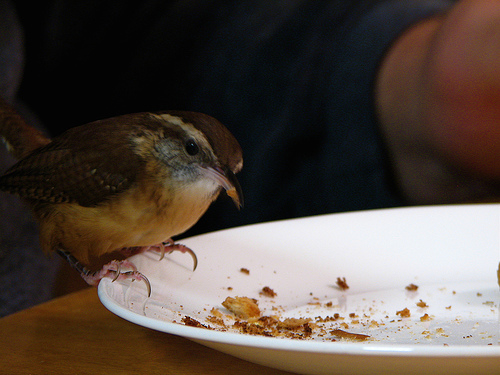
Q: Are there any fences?
A: No, there are no fences.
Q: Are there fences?
A: No, there are no fences.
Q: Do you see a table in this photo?
A: Yes, there is a table.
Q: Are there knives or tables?
A: Yes, there is a table.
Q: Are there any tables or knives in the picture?
A: Yes, there is a table.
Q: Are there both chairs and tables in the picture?
A: No, there is a table but no chairs.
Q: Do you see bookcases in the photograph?
A: No, there are no bookcases.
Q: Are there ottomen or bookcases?
A: No, there are no bookcases or ottomen.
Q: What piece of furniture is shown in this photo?
A: The piece of furniture is a table.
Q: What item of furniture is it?
A: The piece of furniture is a table.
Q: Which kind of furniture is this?
A: This is a table.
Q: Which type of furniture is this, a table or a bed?
A: This is a table.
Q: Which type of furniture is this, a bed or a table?
A: This is a table.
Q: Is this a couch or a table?
A: This is a table.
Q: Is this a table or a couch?
A: This is a table.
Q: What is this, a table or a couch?
A: This is a table.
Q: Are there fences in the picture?
A: No, there are no fences.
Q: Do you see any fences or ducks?
A: No, there are no fences or ducks.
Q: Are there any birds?
A: Yes, there is a bird.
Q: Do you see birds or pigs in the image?
A: Yes, there is a bird.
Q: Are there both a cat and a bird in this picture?
A: No, there is a bird but no cats.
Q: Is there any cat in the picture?
A: No, there are no cats.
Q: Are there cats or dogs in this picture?
A: No, there are no cats or dogs.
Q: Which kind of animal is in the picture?
A: The animal is a bird.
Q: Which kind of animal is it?
A: The animal is a bird.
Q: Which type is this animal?
A: This is a bird.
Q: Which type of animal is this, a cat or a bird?
A: This is a bird.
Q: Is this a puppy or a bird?
A: This is a bird.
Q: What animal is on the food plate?
A: The bird is on the plate.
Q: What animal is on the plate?
A: The bird is on the plate.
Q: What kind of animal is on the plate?
A: The animal is a bird.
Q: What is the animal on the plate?
A: The animal is a bird.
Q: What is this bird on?
A: The bird is on the plate.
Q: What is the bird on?
A: The bird is on the plate.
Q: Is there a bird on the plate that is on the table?
A: Yes, there is a bird on the plate.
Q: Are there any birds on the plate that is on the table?
A: Yes, there is a bird on the plate.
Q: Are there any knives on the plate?
A: No, there is a bird on the plate.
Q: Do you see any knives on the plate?
A: No, there is a bird on the plate.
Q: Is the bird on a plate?
A: Yes, the bird is on a plate.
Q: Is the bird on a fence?
A: No, the bird is on a plate.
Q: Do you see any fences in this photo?
A: No, there are no fences.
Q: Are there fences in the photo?
A: No, there are no fences.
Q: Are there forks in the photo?
A: No, there are no forks.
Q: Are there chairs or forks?
A: No, there are no forks or chairs.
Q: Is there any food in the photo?
A: Yes, there is food.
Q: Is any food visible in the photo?
A: Yes, there is food.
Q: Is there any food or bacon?
A: Yes, there is food.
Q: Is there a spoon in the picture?
A: No, there are no spoons.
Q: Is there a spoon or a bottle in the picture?
A: No, there are no spoons or bottles.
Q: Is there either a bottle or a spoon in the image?
A: No, there are no spoons or bottles.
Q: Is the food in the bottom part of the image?
A: Yes, the food is in the bottom of the image.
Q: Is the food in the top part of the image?
A: No, the food is in the bottom of the image.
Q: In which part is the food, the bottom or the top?
A: The food is in the bottom of the image.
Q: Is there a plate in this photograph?
A: Yes, there is a plate.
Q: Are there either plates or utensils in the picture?
A: Yes, there is a plate.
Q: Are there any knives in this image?
A: No, there are no knives.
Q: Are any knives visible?
A: No, there are no knives.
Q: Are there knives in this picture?
A: No, there are no knives.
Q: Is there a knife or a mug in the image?
A: No, there are no knives or mugs.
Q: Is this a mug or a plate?
A: This is a plate.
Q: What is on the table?
A: The plate is on the table.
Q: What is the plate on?
A: The plate is on the table.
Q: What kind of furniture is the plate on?
A: The plate is on the table.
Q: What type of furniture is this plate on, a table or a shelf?
A: The plate is on a table.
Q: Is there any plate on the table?
A: Yes, there is a plate on the table.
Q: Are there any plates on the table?
A: Yes, there is a plate on the table.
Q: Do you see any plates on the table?
A: Yes, there is a plate on the table.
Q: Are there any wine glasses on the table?
A: No, there is a plate on the table.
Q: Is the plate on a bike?
A: No, the plate is on a table.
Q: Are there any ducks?
A: No, there are no ducks.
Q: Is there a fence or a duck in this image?
A: No, there are no ducks or fences.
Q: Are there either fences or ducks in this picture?
A: No, there are no ducks or fences.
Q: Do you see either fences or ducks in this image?
A: No, there are no ducks or fences.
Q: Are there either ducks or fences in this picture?
A: No, there are no ducks or fences.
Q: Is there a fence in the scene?
A: No, there are no fences.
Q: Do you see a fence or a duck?
A: No, there are no fences or ducks.